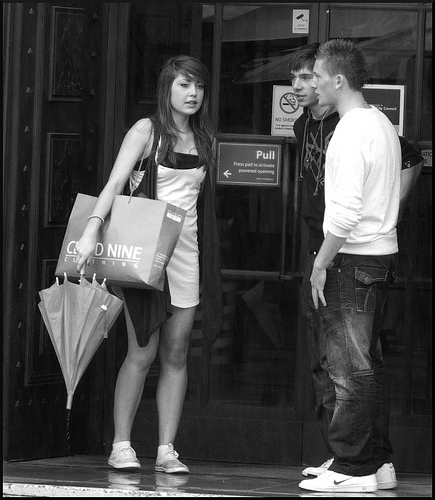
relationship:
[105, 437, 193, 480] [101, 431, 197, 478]
sneakers are on feet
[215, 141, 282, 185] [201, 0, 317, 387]
sign on door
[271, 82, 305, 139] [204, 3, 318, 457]
sign on door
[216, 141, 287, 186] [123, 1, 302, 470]
sign on door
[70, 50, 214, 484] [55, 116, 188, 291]
girl carrying bag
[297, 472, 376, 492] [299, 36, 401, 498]
sneaker on guy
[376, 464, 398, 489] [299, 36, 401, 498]
sneaker on guy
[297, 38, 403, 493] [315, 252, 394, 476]
boy wearing blue jeans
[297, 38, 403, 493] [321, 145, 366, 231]
boy has sleeve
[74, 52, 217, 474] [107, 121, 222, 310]
girl wearing dress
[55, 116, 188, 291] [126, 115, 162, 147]
bag on shoulder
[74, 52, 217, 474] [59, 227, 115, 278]
girl has hand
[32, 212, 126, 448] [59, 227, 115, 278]
umbrella in hand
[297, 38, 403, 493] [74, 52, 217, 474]
boy talking to girl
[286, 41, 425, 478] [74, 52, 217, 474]
guy talking to girl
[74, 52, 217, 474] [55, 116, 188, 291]
girl has bag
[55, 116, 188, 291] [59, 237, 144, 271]
bag has white writing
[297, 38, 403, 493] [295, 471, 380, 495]
boy has sneaker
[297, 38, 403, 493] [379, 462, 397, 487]
boy has sneaker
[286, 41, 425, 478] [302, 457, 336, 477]
guy has sneaker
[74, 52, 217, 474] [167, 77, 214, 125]
girl has face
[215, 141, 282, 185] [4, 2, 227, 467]
sign on door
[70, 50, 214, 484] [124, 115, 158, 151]
girl has shoulder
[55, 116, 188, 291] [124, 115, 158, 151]
bag over shoulder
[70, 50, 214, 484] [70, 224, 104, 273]
girl has hand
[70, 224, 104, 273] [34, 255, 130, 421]
hand holding umbrella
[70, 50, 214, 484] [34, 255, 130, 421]
girl holding umbrella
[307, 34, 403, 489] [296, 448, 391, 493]
boy wearing nike shoes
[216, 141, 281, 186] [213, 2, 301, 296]
sign on door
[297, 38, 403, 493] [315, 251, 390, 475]
boy dressed in blue jeans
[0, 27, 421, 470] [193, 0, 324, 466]
business has door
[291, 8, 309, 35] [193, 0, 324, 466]
notice on door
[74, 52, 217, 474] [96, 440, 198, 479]
girl has feet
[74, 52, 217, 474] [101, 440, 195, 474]
girl wearing shoes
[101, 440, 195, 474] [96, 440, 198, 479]
shoes on feet